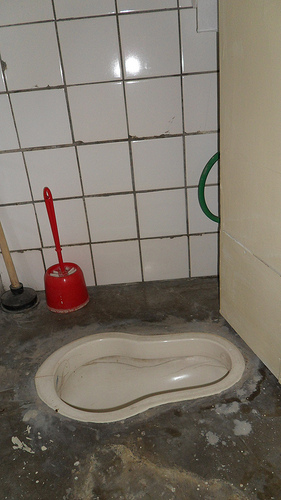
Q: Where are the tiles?
A: On the wall.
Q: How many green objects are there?
A: 1.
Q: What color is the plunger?
A: Black.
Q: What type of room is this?
A: Restroom.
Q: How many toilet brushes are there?
A: 1.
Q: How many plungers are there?
A: 1.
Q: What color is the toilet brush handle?
A: Red.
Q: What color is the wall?
A: White.